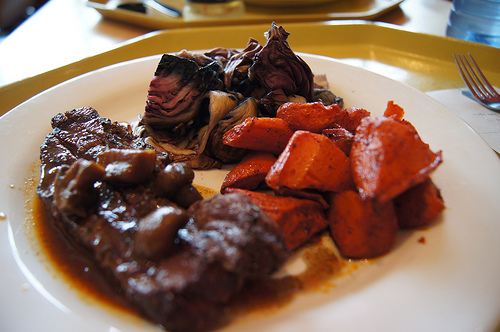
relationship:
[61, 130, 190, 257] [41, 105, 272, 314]
mushrooms on meat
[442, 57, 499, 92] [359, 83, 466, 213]
fork right of plate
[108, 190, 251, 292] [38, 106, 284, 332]
glaze on glaze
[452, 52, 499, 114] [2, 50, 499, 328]
fork next to plate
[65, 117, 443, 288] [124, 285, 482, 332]
plate in background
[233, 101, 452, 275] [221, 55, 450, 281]
carrots are orange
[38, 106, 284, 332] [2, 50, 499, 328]
glaze on plate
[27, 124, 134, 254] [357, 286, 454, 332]
another tray behind first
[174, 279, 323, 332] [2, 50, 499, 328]
sauce on plate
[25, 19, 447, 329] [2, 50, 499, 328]
food on plate